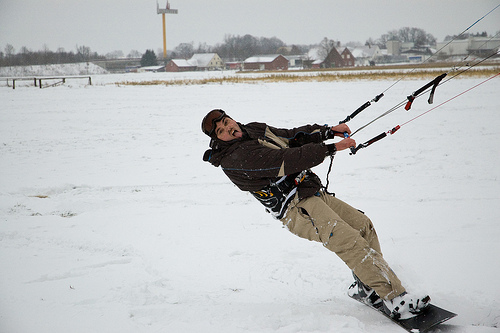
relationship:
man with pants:
[202, 108, 432, 316] [276, 185, 407, 296]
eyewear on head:
[199, 108, 226, 135] [202, 109, 245, 142]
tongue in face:
[232, 131, 242, 138] [209, 115, 243, 141]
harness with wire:
[288, 90, 402, 188] [368, 2, 499, 134]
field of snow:
[2, 76, 497, 331] [406, 173, 499, 289]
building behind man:
[245, 53, 288, 72] [202, 108, 432, 316]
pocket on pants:
[296, 204, 312, 220] [276, 185, 407, 296]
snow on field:
[406, 173, 499, 289] [2, 76, 497, 331]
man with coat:
[202, 108, 432, 316] [202, 123, 333, 205]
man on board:
[202, 108, 432, 316] [349, 279, 457, 330]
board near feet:
[349, 279, 457, 330] [381, 294, 432, 318]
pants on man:
[276, 185, 407, 296] [202, 108, 432, 316]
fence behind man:
[2, 76, 95, 88] [202, 108, 432, 316]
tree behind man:
[140, 51, 160, 68] [202, 108, 432, 316]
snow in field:
[406, 173, 499, 289] [2, 76, 497, 331]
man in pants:
[202, 108, 432, 316] [276, 185, 407, 296]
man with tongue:
[202, 108, 432, 316] [232, 131, 242, 138]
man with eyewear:
[202, 108, 432, 316] [199, 108, 226, 135]